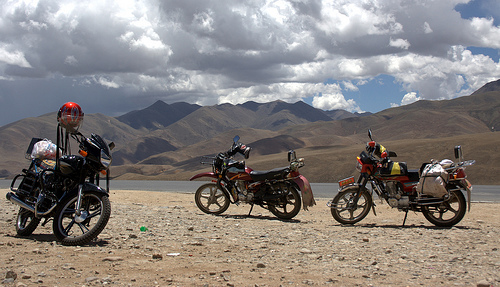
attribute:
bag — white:
[415, 156, 454, 201]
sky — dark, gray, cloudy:
[0, 10, 459, 101]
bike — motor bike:
[321, 125, 466, 233]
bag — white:
[411, 148, 450, 198]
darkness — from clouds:
[142, 106, 176, 117]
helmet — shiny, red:
[50, 94, 87, 134]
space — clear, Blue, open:
[364, 85, 402, 109]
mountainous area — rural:
[10, 61, 474, 177]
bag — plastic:
[24, 140, 64, 159]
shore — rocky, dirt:
[2, 179, 498, 284]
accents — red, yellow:
[365, 138, 389, 155]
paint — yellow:
[389, 159, 402, 173]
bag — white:
[412, 157, 450, 201]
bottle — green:
[138, 223, 148, 230]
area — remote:
[1, 75, 483, 284]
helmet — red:
[54, 100, 85, 130]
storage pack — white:
[412, 159, 452, 202]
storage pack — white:
[433, 156, 454, 170]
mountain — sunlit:
[2, 73, 484, 186]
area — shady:
[110, 95, 201, 131]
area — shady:
[108, 132, 178, 167]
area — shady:
[268, 115, 293, 128]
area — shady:
[265, 96, 334, 123]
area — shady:
[236, 98, 262, 113]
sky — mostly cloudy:
[0, 1, 484, 123]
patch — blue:
[325, 73, 412, 110]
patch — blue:
[299, 91, 321, 104]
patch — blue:
[463, 43, 484, 61]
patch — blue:
[451, 1, 483, 20]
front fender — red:
[187, 170, 240, 205]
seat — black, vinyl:
[246, 165, 289, 181]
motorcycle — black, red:
[189, 132, 314, 219]